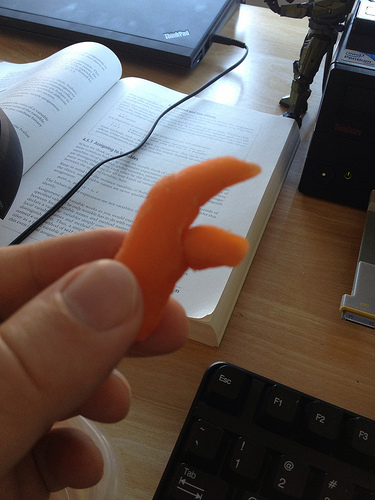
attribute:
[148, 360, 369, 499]
keyboard — black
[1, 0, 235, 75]
laptop — black, closed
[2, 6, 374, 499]
desk — wood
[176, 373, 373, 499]
lettering — white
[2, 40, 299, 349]
book — open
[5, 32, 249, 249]
wire — black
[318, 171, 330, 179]
light — green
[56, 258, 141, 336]
nail — pink, manicured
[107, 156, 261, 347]
object — orange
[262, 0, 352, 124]
figurine — green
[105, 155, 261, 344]
carrot — orange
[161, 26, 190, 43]
name — blue